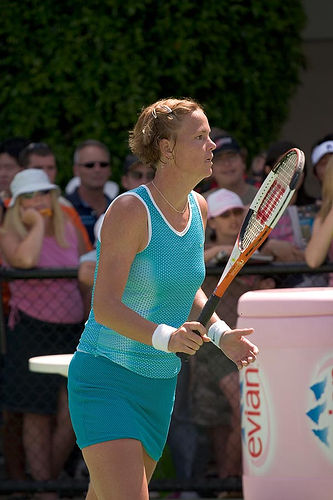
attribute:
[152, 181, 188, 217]
necklace — gold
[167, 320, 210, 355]
hand — gripping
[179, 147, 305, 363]
tennis racket — wilson, wooden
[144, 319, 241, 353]
sweat band — white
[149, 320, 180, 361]
wrist — white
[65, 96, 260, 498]
lindsay davenport — tennis player, female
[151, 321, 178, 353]
wristband — tennis, white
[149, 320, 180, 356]
wrist band — sport, white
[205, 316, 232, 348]
wrist band — white, sport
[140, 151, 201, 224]
necklace — gold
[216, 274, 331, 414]
cooler — evian, white, blue, pink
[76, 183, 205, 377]
shirt — blue, short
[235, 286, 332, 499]
cooler — pink, large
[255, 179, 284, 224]
logo — wilson sporting goods company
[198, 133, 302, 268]
racket — tennis, black, orange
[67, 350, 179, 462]
skirt — tennis, blue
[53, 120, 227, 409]
player — tennis, female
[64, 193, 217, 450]
outfit — turquoise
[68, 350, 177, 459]
tennis skirt — turquoise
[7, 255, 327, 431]
fence — chain link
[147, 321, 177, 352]
band — white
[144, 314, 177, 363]
band — wrist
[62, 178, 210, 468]
clothes — blue, white, tennis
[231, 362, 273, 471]
logo — evian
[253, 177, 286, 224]
letter — w